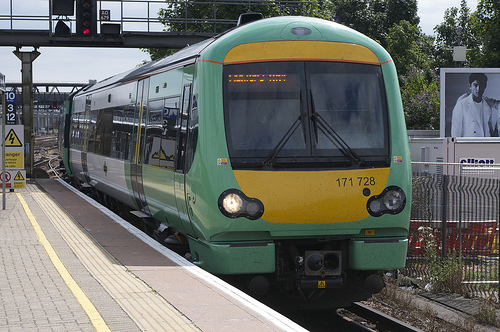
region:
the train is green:
[60, 16, 409, 283]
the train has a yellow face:
[227, 37, 396, 222]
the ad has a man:
[439, 65, 497, 141]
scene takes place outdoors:
[0, 0, 499, 326]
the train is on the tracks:
[58, 13, 412, 286]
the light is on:
[219, 192, 241, 216]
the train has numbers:
[336, 172, 376, 187]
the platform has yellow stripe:
[19, 188, 107, 329]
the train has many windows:
[66, 109, 192, 172]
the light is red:
[81, 29, 93, 39]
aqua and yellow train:
[53, 10, 417, 305]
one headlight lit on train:
[218, 185, 268, 224]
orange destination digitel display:
[224, 66, 294, 89]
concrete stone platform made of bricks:
[1, 168, 301, 325]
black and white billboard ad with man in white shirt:
[438, 64, 498, 131]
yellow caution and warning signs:
[1, 123, 28, 185]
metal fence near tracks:
[405, 173, 499, 308]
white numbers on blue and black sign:
[5, 88, 18, 125]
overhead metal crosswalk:
[4, 0, 277, 187]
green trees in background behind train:
[156, 0, 494, 127]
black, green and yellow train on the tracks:
[54, 14, 413, 308]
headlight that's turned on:
[214, 186, 266, 223]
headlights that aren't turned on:
[363, 183, 409, 218]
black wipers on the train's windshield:
[263, 87, 368, 173]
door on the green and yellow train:
[127, 76, 152, 224]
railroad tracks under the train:
[322, 297, 427, 330]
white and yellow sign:
[1, 122, 28, 194]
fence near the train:
[407, 165, 499, 312]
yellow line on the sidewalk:
[12, 189, 112, 330]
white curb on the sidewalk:
[50, 172, 307, 330]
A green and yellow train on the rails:
[13, 18, 430, 286]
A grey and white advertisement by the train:
[438, 62, 498, 144]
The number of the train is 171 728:
[334, 170, 379, 191]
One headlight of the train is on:
[224, 188, 247, 217]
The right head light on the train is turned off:
[380, 182, 410, 217]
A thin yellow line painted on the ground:
[5, 185, 107, 330]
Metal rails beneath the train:
[356, 298, 418, 329]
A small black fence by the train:
[419, 171, 498, 302]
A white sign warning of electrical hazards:
[2, 122, 27, 152]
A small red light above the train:
[80, 26, 93, 40]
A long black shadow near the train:
[36, 163, 176, 273]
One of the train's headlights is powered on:
[212, 190, 267, 221]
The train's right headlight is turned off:
[380, 183, 411, 228]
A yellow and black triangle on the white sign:
[2, 128, 23, 150]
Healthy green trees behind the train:
[154, 0, 444, 77]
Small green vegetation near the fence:
[427, 243, 467, 291]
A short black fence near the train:
[413, 175, 496, 309]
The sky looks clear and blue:
[41, 51, 118, 76]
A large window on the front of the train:
[219, 57, 407, 174]